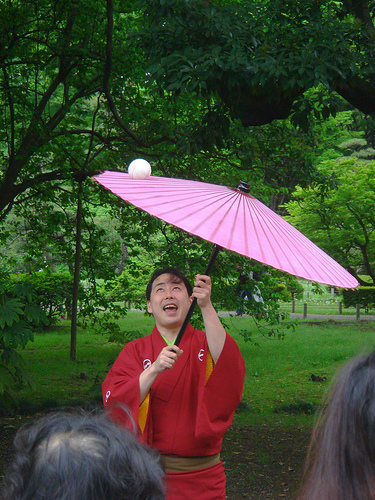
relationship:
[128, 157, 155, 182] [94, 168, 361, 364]
baseball on umbrella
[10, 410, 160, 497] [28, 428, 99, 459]
man has bald spot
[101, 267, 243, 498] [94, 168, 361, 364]
person with umbrella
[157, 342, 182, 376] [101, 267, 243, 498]
right hand of person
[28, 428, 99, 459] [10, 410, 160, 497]
bald spot on man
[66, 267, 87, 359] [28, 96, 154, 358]
trunk of tree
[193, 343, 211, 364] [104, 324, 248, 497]
design on outfit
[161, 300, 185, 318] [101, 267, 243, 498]
mouth of person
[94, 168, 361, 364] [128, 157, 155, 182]
umbrella balances baseball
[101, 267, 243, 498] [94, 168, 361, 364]
person has umbrella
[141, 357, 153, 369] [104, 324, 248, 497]
design on outfit